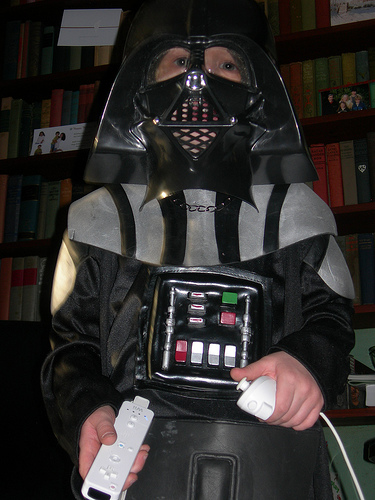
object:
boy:
[41, 1, 356, 498]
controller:
[81, 395, 154, 499]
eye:
[217, 60, 239, 70]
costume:
[40, 1, 357, 498]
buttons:
[221, 291, 237, 304]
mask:
[83, 4, 320, 212]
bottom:
[80, 71, 320, 183]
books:
[7, 97, 22, 160]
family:
[323, 88, 365, 115]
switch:
[174, 339, 188, 361]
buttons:
[219, 310, 237, 326]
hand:
[78, 403, 151, 491]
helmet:
[83, 1, 320, 213]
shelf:
[1, 0, 111, 94]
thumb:
[92, 411, 117, 446]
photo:
[318, 84, 375, 115]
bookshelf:
[0, 1, 374, 497]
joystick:
[235, 375, 277, 421]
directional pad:
[117, 440, 125, 450]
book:
[325, 141, 343, 208]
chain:
[153, 115, 237, 129]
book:
[36, 181, 50, 239]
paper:
[56, 8, 124, 47]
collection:
[1, 1, 374, 323]